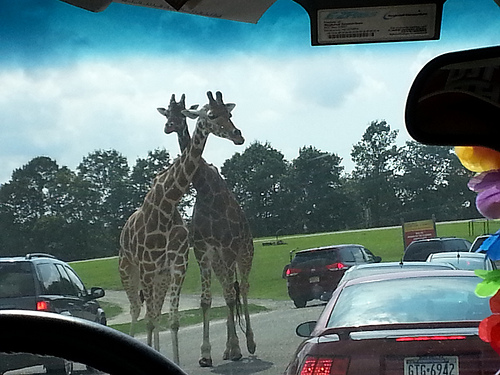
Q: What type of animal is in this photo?
A: Giraffe.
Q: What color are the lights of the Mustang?
A: Red.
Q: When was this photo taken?
A: Day time.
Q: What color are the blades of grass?
A: Green.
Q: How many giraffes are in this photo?
A: Two.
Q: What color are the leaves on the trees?
A: Green.